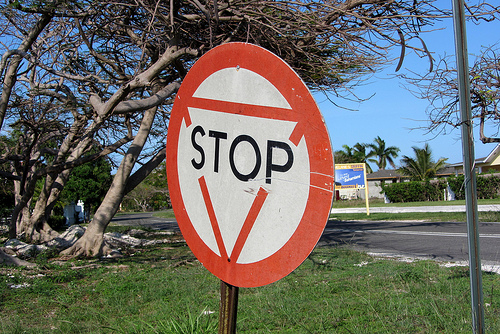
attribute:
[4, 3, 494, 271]
trees — bare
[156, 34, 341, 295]
stop sign — red, white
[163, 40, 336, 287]
sign board — circle-shaped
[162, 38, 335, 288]
border — red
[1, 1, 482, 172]
sky — blue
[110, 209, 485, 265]
road — paved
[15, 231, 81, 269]
rocks — white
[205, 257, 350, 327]
grass — green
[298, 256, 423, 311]
grass — green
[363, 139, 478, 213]
house — across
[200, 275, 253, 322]
pole — displaying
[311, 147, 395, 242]
sign — local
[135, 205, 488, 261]
street — paved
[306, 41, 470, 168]
sky — clear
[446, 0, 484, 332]
pole — grey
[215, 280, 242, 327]
post — metal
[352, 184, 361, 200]
pole — metal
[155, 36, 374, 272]
sign — red, white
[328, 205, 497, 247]
road — lined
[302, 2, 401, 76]
branches — void of leaves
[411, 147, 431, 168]
leaves — green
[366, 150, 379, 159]
leaves — green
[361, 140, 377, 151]
leaves — green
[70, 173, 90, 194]
leaves — green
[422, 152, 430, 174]
leaves — green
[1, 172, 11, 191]
leaves — green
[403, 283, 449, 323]
patch — grass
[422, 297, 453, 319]
growth — uneven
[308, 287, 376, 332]
grass — a patch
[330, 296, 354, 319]
growth — uneven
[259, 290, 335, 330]
grass — a patch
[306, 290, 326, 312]
growth — uneven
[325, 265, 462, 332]
grass — a patch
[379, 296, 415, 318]
growth — uneven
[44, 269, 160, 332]
grass — a patch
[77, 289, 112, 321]
growth — uneven